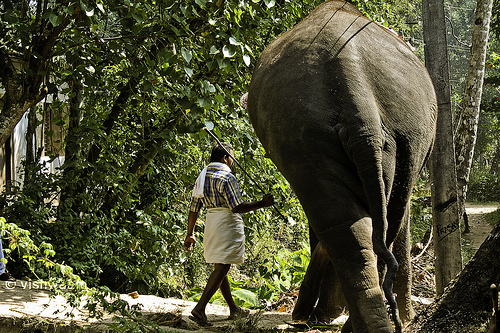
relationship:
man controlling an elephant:
[181, 142, 276, 326] [244, 0, 439, 332]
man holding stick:
[181, 142, 276, 326] [203, 125, 289, 224]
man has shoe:
[181, 142, 276, 326] [2, 266, 17, 280]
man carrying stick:
[181, 142, 276, 326] [203, 125, 289, 224]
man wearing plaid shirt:
[181, 142, 276, 326] [190, 162, 245, 213]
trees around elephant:
[169, 58, 254, 126] [244, 0, 439, 332]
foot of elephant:
[331, 205, 396, 318] [243, 23, 446, 318]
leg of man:
[190, 257, 225, 326] [181, 142, 276, 326]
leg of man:
[214, 271, 247, 320] [181, 142, 276, 326]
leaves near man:
[0, 0, 327, 291] [181, 142, 276, 326]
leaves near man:
[171, 42, 198, 64] [181, 142, 276, 326]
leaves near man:
[204, 37, 246, 76] [181, 142, 276, 326]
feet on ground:
[186, 305, 252, 326] [0, 200, 500, 332]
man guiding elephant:
[181, 142, 276, 326] [244, 0, 439, 332]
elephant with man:
[244, 0, 439, 332] [181, 142, 276, 326]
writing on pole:
[433, 190, 458, 239] [421, 0, 462, 295]